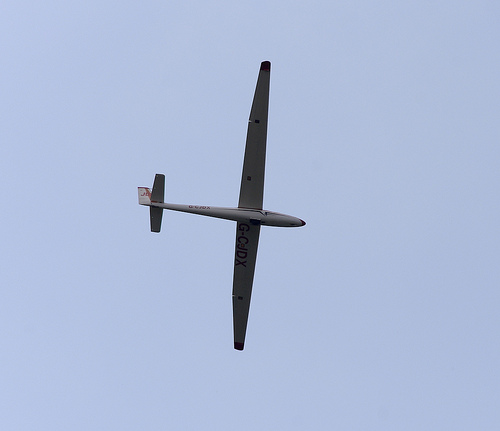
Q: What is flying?
A: An airplane.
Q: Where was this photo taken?
A: Sky.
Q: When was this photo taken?
A: During the day.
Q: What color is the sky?
A: Blue.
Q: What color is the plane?
A: Grey.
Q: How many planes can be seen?
A: Just 1.